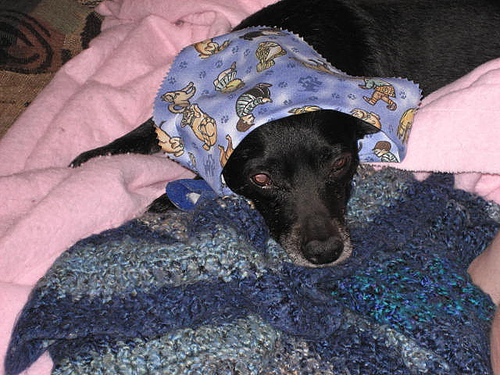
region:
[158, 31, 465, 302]
a dog with a bandana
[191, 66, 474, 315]
a black dog laying down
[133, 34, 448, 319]
a small black dog laying down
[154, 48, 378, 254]
a dog on a blanket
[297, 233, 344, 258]
the dogs nose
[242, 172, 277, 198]
right eye of the dog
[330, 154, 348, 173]
left eye of the dog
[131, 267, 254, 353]
a blue blanket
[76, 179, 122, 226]
the pink blanket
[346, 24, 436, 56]
the dog is black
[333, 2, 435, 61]
the dog has black fur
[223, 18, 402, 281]
dog is laying down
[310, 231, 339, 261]
the dogs nose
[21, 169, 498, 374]
blue crocheted blanket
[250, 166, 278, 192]
right eye of a dog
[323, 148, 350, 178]
left eye of a dog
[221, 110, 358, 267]
face of a black dog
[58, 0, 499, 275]
a black dog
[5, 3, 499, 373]
a pink blanket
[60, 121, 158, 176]
right front paw of a dog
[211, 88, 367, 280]
head of a dog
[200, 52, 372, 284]
the dog is black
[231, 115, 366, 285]
the dog is black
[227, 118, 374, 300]
the dog is black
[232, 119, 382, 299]
the dog is black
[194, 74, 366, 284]
the dog is resting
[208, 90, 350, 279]
the dog is resting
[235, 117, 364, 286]
the dog is resting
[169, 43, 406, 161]
shirt on a dogs head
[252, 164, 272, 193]
dog with brown eyes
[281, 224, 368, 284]
dog with a white mouth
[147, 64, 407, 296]
a view of dog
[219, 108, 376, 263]
a view of face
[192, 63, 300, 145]
a view of cloth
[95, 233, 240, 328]
a view of blue dress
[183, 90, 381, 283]
a dog with dress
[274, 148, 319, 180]
a view of fur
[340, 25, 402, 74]
a view of hairs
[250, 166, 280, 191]
right brown dog eye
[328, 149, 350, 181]
left brown dog eye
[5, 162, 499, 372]
dog mouth resting on croucheted blanket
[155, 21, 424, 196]
blue bib with cartoon characters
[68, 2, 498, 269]
sleepy dog laying on blankets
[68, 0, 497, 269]
black dog laying on pink blanket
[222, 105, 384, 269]
dog head resting on knit blanket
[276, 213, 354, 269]
black dog nose and white mouth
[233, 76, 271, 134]
cartoon boy wearing blue shirt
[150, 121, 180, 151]
animated character on the blue scarf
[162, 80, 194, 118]
animated character on the blue scarf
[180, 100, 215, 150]
animated character on the blue scarf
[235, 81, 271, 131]
animated character on the blue scarf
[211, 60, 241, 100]
animated character on the blue scarf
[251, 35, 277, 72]
animated character on the blue scarf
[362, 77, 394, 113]
animated character on the blue scarf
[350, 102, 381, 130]
animated character on the blue scarf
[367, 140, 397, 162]
animated character on the blue scarf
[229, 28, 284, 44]
animated character on the blue scarf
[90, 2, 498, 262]
a black dog laying down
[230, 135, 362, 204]
a dog with brown eyes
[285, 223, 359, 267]
white fur around the nose